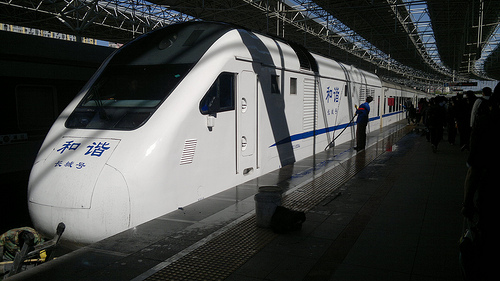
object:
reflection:
[355, 149, 366, 170]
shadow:
[238, 29, 297, 167]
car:
[26, 21, 437, 245]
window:
[271, 74, 281, 93]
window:
[384, 95, 386, 113]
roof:
[3, 0, 498, 91]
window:
[389, 96, 393, 113]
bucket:
[254, 186, 285, 228]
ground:
[19, 121, 446, 275]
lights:
[333, 22, 336, 24]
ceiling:
[292, 0, 498, 45]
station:
[4, 1, 498, 275]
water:
[290, 161, 334, 180]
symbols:
[84, 141, 110, 157]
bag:
[458, 215, 477, 268]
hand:
[461, 205, 474, 218]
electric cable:
[3, 2, 136, 28]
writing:
[64, 161, 75, 168]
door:
[236, 70, 260, 175]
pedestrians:
[404, 98, 417, 126]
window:
[66, 41, 215, 130]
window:
[200, 71, 236, 114]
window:
[290, 77, 297, 94]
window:
[344, 85, 348, 96]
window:
[377, 96, 380, 117]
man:
[353, 96, 374, 150]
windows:
[393, 96, 396, 112]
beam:
[145, 0, 306, 22]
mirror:
[207, 95, 221, 131]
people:
[423, 97, 449, 153]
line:
[130, 208, 258, 280]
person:
[415, 97, 428, 126]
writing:
[54, 160, 63, 167]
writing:
[57, 141, 81, 154]